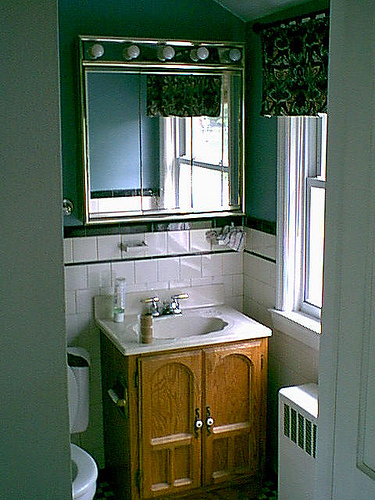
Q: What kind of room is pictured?
A: It is a bathroom.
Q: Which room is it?
A: It is a bathroom.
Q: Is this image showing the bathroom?
A: Yes, it is showing the bathroom.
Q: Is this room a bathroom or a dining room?
A: It is a bathroom.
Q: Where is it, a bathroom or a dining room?
A: It is a bathroom.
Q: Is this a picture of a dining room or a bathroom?
A: It is showing a bathroom.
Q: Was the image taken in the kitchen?
A: No, the picture was taken in the bathroom.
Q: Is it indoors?
A: Yes, it is indoors.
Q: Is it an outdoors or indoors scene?
A: It is indoors.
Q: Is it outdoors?
A: No, it is indoors.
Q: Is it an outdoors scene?
A: No, it is indoors.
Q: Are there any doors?
A: Yes, there are doors.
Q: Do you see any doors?
A: Yes, there are doors.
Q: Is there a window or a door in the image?
A: Yes, there are doors.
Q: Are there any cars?
A: No, there are no cars.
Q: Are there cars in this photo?
A: No, there are no cars.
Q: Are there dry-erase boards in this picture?
A: No, there are no dry-erase boards.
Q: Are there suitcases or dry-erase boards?
A: No, there are no dry-erase boards or suitcases.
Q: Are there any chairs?
A: No, there are no chairs.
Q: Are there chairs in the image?
A: No, there are no chairs.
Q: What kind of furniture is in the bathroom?
A: The piece of furniture is a medicine cabinet.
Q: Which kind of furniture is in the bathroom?
A: The piece of furniture is a medicine cabinet.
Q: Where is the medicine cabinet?
A: The medicine cabinet is in the bathroom.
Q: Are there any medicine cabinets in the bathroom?
A: Yes, there is a medicine cabinet in the bathroom.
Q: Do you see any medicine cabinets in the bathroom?
A: Yes, there is a medicine cabinet in the bathroom.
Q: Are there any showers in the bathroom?
A: No, there is a medicine cabinet in the bathroom.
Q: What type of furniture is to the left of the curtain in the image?
A: The piece of furniture is a medicine cabinet.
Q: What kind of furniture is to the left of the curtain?
A: The piece of furniture is a medicine cabinet.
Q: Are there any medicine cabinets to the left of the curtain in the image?
A: Yes, there is a medicine cabinet to the left of the curtain.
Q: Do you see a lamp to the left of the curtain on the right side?
A: No, there is a medicine cabinet to the left of the curtain.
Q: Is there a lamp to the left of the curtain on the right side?
A: No, there is a medicine cabinet to the left of the curtain.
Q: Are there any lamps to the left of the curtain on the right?
A: No, there is a medicine cabinet to the left of the curtain.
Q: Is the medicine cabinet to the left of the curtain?
A: Yes, the medicine cabinet is to the left of the curtain.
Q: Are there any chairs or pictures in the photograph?
A: No, there are no chairs or pictures.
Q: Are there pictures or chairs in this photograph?
A: No, there are no chairs or pictures.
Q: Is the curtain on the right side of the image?
A: Yes, the curtain is on the right of the image.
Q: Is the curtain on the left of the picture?
A: No, the curtain is on the right of the image.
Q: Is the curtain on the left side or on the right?
A: The curtain is on the right of the image.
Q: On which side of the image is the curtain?
A: The curtain is on the right of the image.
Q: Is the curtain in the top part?
A: Yes, the curtain is in the top of the image.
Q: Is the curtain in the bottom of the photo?
A: No, the curtain is in the top of the image.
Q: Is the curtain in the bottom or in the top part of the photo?
A: The curtain is in the top of the image.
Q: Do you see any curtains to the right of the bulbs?
A: Yes, there is a curtain to the right of the bulbs.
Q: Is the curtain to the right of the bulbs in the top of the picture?
A: Yes, the curtain is to the right of the light bulbs.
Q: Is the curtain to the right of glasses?
A: No, the curtain is to the right of the light bulbs.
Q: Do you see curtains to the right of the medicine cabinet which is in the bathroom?
A: Yes, there is a curtain to the right of the medicine cabinet.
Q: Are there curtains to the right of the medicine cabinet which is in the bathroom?
A: Yes, there is a curtain to the right of the medicine cabinet.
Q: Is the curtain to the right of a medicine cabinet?
A: Yes, the curtain is to the right of a medicine cabinet.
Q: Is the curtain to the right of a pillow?
A: No, the curtain is to the right of a medicine cabinet.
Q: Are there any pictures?
A: No, there are no pictures.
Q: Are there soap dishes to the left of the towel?
A: Yes, there is a soap dish to the left of the towel.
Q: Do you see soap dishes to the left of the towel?
A: Yes, there is a soap dish to the left of the towel.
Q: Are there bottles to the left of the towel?
A: No, there is a soap dish to the left of the towel.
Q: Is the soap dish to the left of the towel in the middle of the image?
A: Yes, the soap dish is to the left of the towel.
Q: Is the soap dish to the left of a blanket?
A: No, the soap dish is to the left of the towel.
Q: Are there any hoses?
A: No, there are no hoses.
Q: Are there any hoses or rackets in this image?
A: No, there are no hoses or rackets.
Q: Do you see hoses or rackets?
A: No, there are no hoses or rackets.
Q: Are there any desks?
A: No, there are no desks.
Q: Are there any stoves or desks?
A: No, there are no desks or stoves.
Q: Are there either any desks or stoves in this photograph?
A: No, there are no desks or stoves.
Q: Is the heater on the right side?
A: Yes, the heater is on the right of the image.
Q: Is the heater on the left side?
A: No, the heater is on the right of the image.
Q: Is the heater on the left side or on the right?
A: The heater is on the right of the image.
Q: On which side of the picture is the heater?
A: The heater is on the right of the image.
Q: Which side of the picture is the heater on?
A: The heater is on the right of the image.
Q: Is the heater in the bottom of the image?
A: Yes, the heater is in the bottom of the image.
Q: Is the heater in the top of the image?
A: No, the heater is in the bottom of the image.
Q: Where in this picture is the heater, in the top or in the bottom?
A: The heater is in the bottom of the image.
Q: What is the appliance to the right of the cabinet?
A: The appliance is a heater.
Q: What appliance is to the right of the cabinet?
A: The appliance is a heater.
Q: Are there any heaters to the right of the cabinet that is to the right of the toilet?
A: Yes, there is a heater to the right of the cabinet.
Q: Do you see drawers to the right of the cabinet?
A: No, there is a heater to the right of the cabinet.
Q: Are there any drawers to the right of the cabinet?
A: No, there is a heater to the right of the cabinet.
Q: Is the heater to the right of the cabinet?
A: Yes, the heater is to the right of the cabinet.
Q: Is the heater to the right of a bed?
A: No, the heater is to the right of the cabinet.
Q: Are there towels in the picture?
A: Yes, there is a towel.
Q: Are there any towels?
A: Yes, there is a towel.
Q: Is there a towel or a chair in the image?
A: Yes, there is a towel.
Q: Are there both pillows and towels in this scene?
A: No, there is a towel but no pillows.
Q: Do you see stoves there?
A: No, there are no stoves.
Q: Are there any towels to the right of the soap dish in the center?
A: Yes, there is a towel to the right of the soap dish.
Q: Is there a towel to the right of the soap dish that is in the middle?
A: Yes, there is a towel to the right of the soap dish.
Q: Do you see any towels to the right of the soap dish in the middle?
A: Yes, there is a towel to the right of the soap dish.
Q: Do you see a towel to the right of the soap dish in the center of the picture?
A: Yes, there is a towel to the right of the soap dish.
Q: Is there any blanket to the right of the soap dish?
A: No, there is a towel to the right of the soap dish.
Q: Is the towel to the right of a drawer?
A: No, the towel is to the right of a soap dish.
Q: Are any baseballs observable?
A: No, there are no baseballs.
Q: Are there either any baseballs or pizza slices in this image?
A: No, there are no baseballs or pizza slices.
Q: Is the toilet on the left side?
A: Yes, the toilet is on the left of the image.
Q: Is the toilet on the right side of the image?
A: No, the toilet is on the left of the image.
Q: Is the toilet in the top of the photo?
A: No, the toilet is in the bottom of the image.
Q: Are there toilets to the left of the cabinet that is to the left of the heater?
A: Yes, there is a toilet to the left of the cabinet.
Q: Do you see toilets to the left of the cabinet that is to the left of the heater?
A: Yes, there is a toilet to the left of the cabinet.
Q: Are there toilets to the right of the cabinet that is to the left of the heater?
A: No, the toilet is to the left of the cabinet.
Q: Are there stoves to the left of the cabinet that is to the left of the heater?
A: No, there is a toilet to the left of the cabinet.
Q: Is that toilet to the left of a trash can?
A: No, the toilet is to the left of a cabinet.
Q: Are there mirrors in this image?
A: Yes, there is a mirror.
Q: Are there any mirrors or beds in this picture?
A: Yes, there is a mirror.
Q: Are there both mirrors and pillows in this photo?
A: No, there is a mirror but no pillows.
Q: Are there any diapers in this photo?
A: No, there are no diapers.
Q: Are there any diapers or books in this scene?
A: No, there are no diapers or books.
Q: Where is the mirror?
A: The mirror is in the bathroom.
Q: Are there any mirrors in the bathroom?
A: Yes, there is a mirror in the bathroom.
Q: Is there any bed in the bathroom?
A: No, there is a mirror in the bathroom.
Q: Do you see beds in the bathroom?
A: No, there is a mirror in the bathroom.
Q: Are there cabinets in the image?
A: Yes, there is a cabinet.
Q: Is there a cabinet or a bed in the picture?
A: Yes, there is a cabinet.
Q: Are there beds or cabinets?
A: Yes, there is a cabinet.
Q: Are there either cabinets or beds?
A: Yes, there is a cabinet.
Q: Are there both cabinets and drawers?
A: No, there is a cabinet but no drawers.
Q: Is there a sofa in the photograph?
A: No, there are no sofas.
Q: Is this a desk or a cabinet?
A: This is a cabinet.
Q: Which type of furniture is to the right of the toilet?
A: The piece of furniture is a cabinet.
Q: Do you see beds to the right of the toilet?
A: No, there is a cabinet to the right of the toilet.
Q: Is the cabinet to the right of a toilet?
A: Yes, the cabinet is to the right of a toilet.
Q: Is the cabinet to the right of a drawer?
A: No, the cabinet is to the right of a toilet.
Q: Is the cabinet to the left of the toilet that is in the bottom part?
A: No, the cabinet is to the right of the toilet.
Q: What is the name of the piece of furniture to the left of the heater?
A: The piece of furniture is a cabinet.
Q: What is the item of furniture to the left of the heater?
A: The piece of furniture is a cabinet.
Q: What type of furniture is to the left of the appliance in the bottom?
A: The piece of furniture is a cabinet.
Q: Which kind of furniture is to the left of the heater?
A: The piece of furniture is a cabinet.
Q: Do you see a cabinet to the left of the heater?
A: Yes, there is a cabinet to the left of the heater.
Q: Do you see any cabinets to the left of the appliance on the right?
A: Yes, there is a cabinet to the left of the heater.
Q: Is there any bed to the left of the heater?
A: No, there is a cabinet to the left of the heater.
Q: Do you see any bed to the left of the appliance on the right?
A: No, there is a cabinet to the left of the heater.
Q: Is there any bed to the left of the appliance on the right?
A: No, there is a cabinet to the left of the heater.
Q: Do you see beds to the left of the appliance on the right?
A: No, there is a cabinet to the left of the heater.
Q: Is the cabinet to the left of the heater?
A: Yes, the cabinet is to the left of the heater.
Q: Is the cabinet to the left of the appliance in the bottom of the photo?
A: Yes, the cabinet is to the left of the heater.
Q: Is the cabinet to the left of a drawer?
A: No, the cabinet is to the left of the heater.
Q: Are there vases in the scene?
A: No, there are no vases.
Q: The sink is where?
A: The sink is in the bathroom.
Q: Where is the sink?
A: The sink is in the bathroom.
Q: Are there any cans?
A: No, there are no cans.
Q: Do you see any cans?
A: No, there are no cans.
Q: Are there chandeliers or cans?
A: No, there are no cans or chandeliers.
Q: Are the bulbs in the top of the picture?
A: Yes, the bulbs are in the top of the image.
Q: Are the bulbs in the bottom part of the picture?
A: No, the bulbs are in the top of the image.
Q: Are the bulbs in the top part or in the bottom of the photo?
A: The bulbs are in the top of the image.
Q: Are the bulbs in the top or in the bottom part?
A: The bulbs are in the top of the image.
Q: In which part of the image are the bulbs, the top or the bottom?
A: The bulbs are in the top of the image.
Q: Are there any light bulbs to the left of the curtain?
A: Yes, there are light bulbs to the left of the curtain.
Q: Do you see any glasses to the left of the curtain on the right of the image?
A: No, there are light bulbs to the left of the curtain.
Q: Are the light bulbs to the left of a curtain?
A: Yes, the light bulbs are to the left of a curtain.